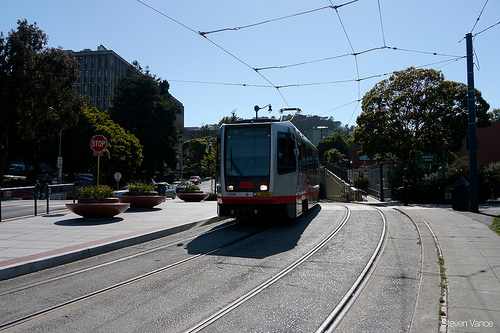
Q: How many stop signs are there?
A: One.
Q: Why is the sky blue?
A: It is day time.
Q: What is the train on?
A: The track.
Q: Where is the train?
A: On the track.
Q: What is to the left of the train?
A: Trees.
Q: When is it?
A: Day time.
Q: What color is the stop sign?
A: Red.